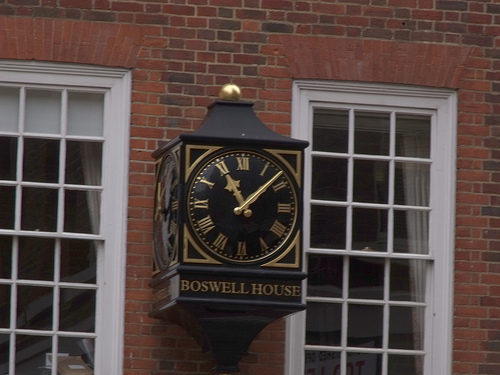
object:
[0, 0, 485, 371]
outside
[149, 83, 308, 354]
clock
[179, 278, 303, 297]
boswell house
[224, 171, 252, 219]
hand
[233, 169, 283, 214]
hand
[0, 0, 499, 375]
wall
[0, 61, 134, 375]
window pane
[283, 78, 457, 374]
window pane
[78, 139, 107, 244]
curtain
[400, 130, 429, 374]
curtain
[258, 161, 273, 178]
number i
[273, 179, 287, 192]
number ii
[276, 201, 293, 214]
number iii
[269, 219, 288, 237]
number iiii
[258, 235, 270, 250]
number v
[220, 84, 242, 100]
ball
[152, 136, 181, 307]
side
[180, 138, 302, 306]
side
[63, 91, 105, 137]
square pane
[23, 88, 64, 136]
square pane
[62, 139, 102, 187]
square pane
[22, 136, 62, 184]
square pane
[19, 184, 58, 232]
square pane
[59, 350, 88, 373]
package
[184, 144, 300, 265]
clock face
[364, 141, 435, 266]
reflection